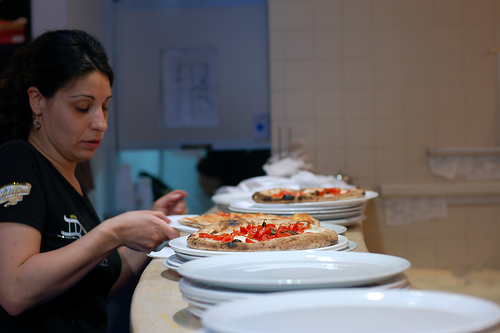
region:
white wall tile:
[271, 7, 496, 145]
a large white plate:
[172, 248, 412, 289]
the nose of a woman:
[87, 103, 109, 133]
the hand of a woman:
[104, 208, 176, 255]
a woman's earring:
[29, 110, 44, 128]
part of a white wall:
[118, 2, 259, 46]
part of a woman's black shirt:
[0, 141, 127, 331]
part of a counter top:
[129, 254, 199, 331]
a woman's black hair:
[1, 30, 113, 138]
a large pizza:
[180, 221, 343, 251]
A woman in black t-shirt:
[0, 28, 181, 331]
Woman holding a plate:
[1, 30, 183, 330]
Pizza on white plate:
[182, 221, 335, 247]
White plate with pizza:
[167, 220, 348, 255]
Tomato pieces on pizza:
[196, 219, 308, 325]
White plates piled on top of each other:
[174, 254, 424, 331]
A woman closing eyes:
[0, 23, 117, 164]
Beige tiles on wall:
[261, 0, 498, 297]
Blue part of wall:
[31, 0, 271, 160]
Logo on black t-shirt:
[0, 183, 33, 206]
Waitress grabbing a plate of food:
[0, 28, 187, 331]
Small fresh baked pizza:
[167, 217, 349, 252]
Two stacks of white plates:
[177, 251, 496, 331]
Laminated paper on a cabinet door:
[156, 40, 223, 133]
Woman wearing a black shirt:
[2, 28, 187, 331]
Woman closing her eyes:
[0, 28, 187, 330]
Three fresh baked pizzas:
[177, 181, 365, 253]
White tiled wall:
[266, 1, 498, 273]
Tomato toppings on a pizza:
[193, 221, 314, 245]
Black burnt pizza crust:
[223, 238, 243, 251]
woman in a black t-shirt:
[0, 16, 191, 330]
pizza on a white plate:
[154, 201, 354, 268]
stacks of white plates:
[177, 242, 492, 332]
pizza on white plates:
[167, 147, 378, 265]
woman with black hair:
[6, 30, 173, 330]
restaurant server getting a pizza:
[6, 27, 161, 327]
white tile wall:
[262, 4, 498, 260]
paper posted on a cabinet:
[129, 35, 249, 139]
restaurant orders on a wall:
[378, 133, 498, 255]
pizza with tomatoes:
[170, 214, 365, 269]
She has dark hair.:
[3, 21, 112, 108]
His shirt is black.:
[10, 141, 126, 319]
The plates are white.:
[173, 250, 490, 330]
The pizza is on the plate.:
[182, 216, 341, 256]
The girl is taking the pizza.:
[10, 32, 413, 319]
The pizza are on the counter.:
[183, 164, 377, 271]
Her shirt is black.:
[4, 132, 134, 332]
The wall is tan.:
[275, 4, 482, 249]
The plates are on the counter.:
[141, 136, 486, 323]